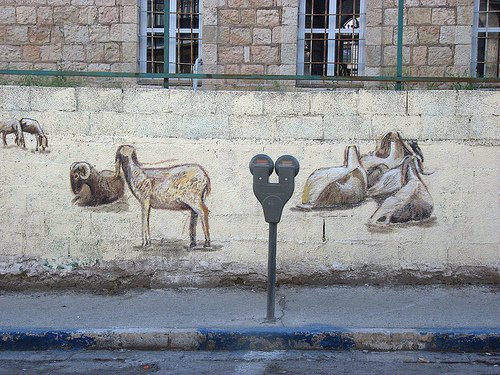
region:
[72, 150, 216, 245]
drawings on the wall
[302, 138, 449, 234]
drawings of animals on the wall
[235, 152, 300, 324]
a parking meter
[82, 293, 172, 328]
the sidewalk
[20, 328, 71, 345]
blue painting on the curb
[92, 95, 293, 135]
a brick wall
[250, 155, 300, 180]
two meters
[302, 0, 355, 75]
windows on the building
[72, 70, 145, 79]
a green pole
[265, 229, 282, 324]
a pole on the meter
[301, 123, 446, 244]
drawing of three goats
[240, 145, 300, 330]
parking meter on the sidewalk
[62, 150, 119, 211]
drawing of a ram on the wall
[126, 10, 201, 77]
windows on the building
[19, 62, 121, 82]
green pole above the wall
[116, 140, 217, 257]
drawing of a goat on the wall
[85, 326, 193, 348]
gray on the sidewalk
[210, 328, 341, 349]
blue on the sidewalk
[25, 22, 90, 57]
brown brick with cracks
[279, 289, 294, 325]
crack in the sidewalk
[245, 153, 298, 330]
dual parking meter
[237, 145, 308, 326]
black metal parking meter on sidewalk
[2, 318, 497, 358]
blue paint on sidewalk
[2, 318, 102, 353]
faded blue paint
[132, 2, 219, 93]
window with metal bars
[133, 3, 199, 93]
window with white frame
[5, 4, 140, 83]
red square bricks in the wall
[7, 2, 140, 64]
red brick wall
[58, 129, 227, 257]
rams painted on the wall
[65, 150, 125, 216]
brown ram with white horns painting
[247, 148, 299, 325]
A lone, two part parking meter.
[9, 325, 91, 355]
Peeling blue paint on the curb.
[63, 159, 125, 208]
A mural of a sitting buffalo.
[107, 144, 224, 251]
A mural of a standing goat.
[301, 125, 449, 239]
A mural of a group of goats.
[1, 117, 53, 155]
A mural of two grazing goats.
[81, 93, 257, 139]
A dingy beige colored brick wall.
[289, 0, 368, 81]
A window above the wall.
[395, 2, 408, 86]
A green pole above the wall.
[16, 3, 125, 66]
A standard brick wall.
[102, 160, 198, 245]
This is a painting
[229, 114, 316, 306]
This is a meter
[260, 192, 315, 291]
The meter is for parking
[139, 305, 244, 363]
This is a sidewalk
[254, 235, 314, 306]
The pole is made of metal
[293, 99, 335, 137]
This is a brick wall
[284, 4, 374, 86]
This is a window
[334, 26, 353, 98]
This is a metal bar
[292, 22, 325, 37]
The metal is rusting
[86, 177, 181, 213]
This is a sheep